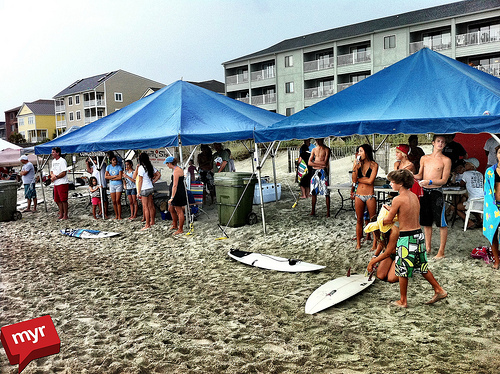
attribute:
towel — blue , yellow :
[477, 166, 499, 236]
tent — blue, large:
[35, 78, 287, 227]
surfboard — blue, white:
[59, 227, 120, 237]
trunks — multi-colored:
[401, 200, 453, 267]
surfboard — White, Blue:
[60, 227, 117, 239]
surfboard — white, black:
[61, 227, 122, 238]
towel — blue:
[60, 227, 100, 237]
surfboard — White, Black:
[229, 226, 434, 358]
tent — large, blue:
[249, 44, 499, 236]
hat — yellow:
[358, 208, 395, 231]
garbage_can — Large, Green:
[212, 165, 262, 230]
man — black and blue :
[410, 129, 465, 276]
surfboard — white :
[54, 220, 125, 250]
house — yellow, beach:
[15, 101, 55, 143]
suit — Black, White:
[348, 157, 378, 198]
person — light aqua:
[478, 142, 499, 269]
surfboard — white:
[299, 267, 379, 319]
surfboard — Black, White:
[225, 245, 326, 273]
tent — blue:
[243, 35, 499, 250]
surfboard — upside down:
[309, 259, 391, 317]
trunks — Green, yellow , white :
[373, 228, 448, 296]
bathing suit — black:
[166, 167, 181, 217]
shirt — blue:
[104, 162, 129, 180]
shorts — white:
[106, 182, 126, 193]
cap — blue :
[164, 155, 184, 165]